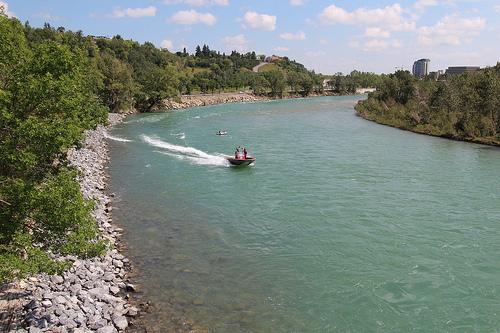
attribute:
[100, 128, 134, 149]
waves — white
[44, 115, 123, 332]
riverbank — rocky, grey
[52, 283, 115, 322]
rocks — large, grey, dark brown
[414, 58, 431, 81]
skyscraper — round, tall, grey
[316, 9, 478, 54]
clouds — fluffy, white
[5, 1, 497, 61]
sky — blue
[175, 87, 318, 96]
roadway — small, grey, curvy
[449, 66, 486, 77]
building top — brown, dark grey, flat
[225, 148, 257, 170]
speedboat — small, red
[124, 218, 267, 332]
rocks — wet, large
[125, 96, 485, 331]
river — blue, greenish-blue, large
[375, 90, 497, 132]
trees — dark green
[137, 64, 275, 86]
trees — dark green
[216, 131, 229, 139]
mini-boat — small